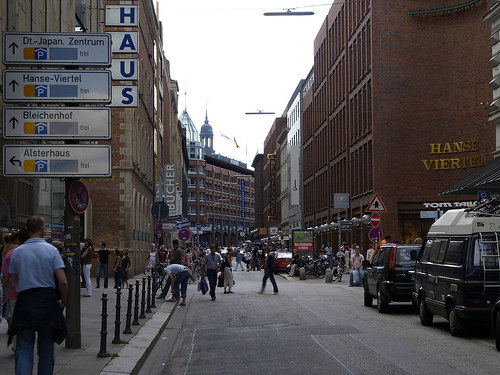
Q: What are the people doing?
A: Walking.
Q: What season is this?
A: Summer.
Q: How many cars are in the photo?
A: Three.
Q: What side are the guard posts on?
A: Left.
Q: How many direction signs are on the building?
A: Four.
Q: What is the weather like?
A: Overcast.